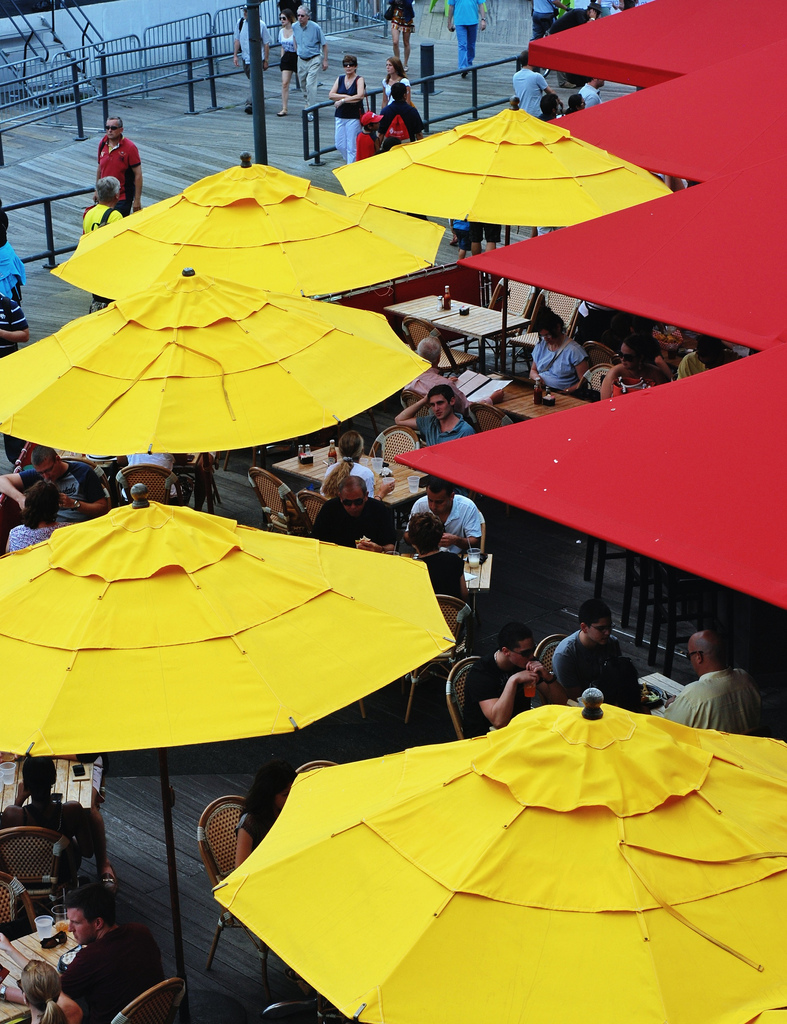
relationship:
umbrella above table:
[0, 485, 457, 1024] [1, 915, 79, 1020]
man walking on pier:
[95, 115, 142, 218] [8, 0, 530, 339]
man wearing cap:
[347, 106, 387, 161] [356, 108, 387, 129]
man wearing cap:
[351, 106, 382, 161] [356, 108, 386, 126]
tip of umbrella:
[121, 473, 146, 493] [33, 510, 412, 674]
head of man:
[61, 897, 113, 939] [56, 900, 163, 1004]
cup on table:
[23, 910, 63, 935] [1, 927, 146, 995]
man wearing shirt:
[552, 593, 623, 703] [546, 629, 626, 701]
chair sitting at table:
[105, 971, 186, 1021] [1, 915, 79, 1020]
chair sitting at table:
[251, 984, 323, 1021] [317, 993, 344, 1021]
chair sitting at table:
[0, 824, 68, 925] [2, 754, 96, 818]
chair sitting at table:
[243, 463, 301, 531] [270, 442, 430, 512]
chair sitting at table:
[486, 276, 537, 373] [384, 289, 531, 371]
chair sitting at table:
[2, 821, 72, 916] [2, 754, 96, 818]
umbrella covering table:
[207, 682, 763, 1018] [307, 997, 341, 1021]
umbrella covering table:
[2, 479, 457, 1021] [2, 754, 96, 818]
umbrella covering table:
[389, 324, 763, 607] [632, 662, 687, 720]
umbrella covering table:
[327, 93, 676, 377] [384, 289, 531, 371]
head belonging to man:
[423, 380, 460, 421] [389, 384, 476, 445]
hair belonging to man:
[426, 380, 454, 400] [389, 384, 476, 445]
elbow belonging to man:
[390, 412, 408, 426] [392, 379, 474, 447]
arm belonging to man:
[467, 665, 539, 729] [456, 616, 570, 737]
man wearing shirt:
[392, 379, 474, 447] [414, 407, 472, 445]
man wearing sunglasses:
[312, 476, 396, 555] [340, 490, 368, 511]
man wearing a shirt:
[320, 475, 402, 553] [317, 497, 405, 549]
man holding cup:
[462, 625, 547, 728] [517, 668, 541, 699]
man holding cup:
[462, 625, 547, 728] [517, 665, 545, 707]